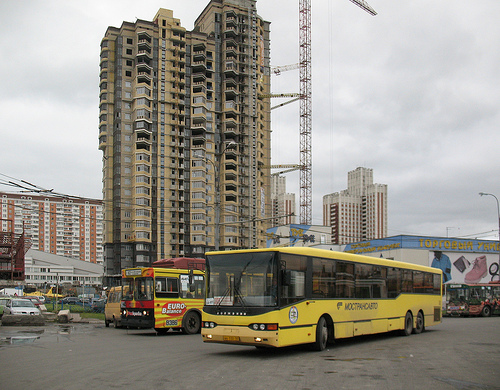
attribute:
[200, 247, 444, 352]
bus — yellow, passenger, parked, light yellow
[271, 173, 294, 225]
building — yellow, large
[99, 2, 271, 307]
building — tall, unfinished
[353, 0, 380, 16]
crane — tall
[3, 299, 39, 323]
car — white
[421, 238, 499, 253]
writing — yellow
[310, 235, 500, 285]
building — white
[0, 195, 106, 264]
building — striped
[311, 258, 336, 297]
window — black, tinted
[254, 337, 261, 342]
light — white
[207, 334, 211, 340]
light — white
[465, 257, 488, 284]
shoe — brown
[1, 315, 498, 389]
road — paved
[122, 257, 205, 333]
bus — red, public service